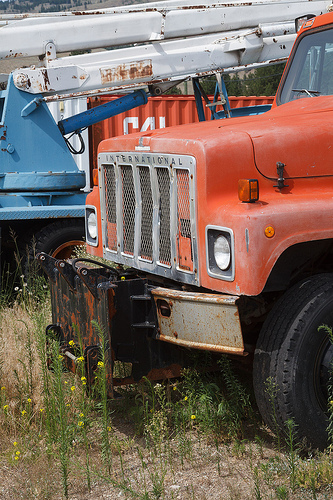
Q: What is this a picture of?
A: A truck.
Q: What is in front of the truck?
A: Wildflowers.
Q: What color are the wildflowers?
A: Yellow.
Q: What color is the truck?
A: Orange.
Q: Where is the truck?
A: In a field.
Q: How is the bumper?
A: Rusty.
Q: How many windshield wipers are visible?
A: One.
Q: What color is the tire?
A: Black.